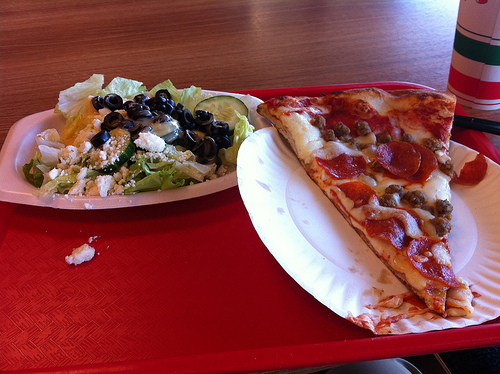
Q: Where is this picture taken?
A: A restaurant.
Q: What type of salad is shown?
A: Greek.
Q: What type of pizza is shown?
A: Pepperoni.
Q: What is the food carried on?
A: A tray.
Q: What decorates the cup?
A: Striped.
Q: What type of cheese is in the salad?
A: Feta.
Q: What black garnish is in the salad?
A: Olives.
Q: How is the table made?
A: Of wood.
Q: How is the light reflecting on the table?
A: The table has a shiny surface.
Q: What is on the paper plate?
A: A piece of pizza.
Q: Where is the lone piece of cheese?
A: On the red tray.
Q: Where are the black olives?
A: On top of the salad.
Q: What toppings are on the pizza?
A: Pepperoni and sausage.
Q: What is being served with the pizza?
A: A side salad.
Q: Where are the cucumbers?
A: In the salad.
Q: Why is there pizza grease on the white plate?
A: The pizza is messy.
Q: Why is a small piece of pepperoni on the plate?
A: It fell off of the pizza.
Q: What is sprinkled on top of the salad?
A: White cheese.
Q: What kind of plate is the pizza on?
A: A paper plate.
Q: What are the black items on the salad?
A: Olives.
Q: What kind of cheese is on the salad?
A: Feta.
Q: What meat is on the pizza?
A: Sausage and pepperoni.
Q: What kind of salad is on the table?
A: Greek salad.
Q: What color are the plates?
A: White.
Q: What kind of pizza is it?
A: Pepperoni and sausage.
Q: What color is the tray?
A: Red.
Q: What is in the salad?
A: Black olives and cheese.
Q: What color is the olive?
A: Black.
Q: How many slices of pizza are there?
A: One.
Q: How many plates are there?
A: Two.